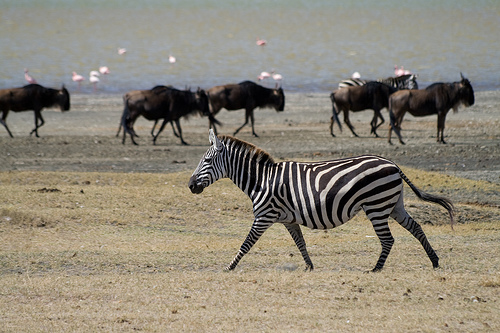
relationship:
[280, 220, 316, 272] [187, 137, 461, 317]
leg of zebra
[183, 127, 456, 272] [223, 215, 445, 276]
zebra has legs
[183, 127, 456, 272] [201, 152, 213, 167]
zebra has eye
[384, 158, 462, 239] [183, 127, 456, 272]
tail of zebra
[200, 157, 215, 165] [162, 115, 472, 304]
eye of zebra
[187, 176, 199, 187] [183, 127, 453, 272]
nose of zebra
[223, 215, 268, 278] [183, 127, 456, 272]
front leg of zebra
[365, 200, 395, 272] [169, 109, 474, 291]
hind leg of zebra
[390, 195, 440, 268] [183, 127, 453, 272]
leg of zebra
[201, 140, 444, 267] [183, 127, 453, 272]
coat on zebra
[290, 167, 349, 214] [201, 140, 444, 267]
zebra stripes on coat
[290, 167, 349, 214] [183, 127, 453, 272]
zebra stripes on zebra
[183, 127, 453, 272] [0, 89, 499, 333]
zebra on ground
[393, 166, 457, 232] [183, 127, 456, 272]
tail of zebra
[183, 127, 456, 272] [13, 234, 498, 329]
zebra on ground